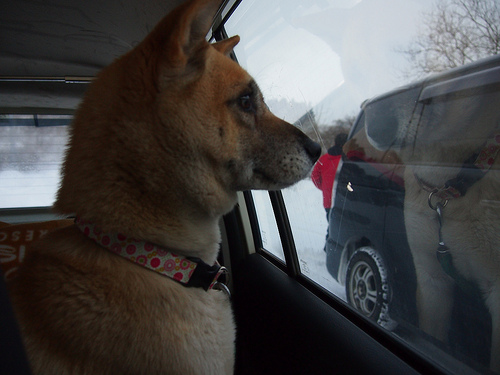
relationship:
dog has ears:
[2, 4, 320, 374] [167, 2, 245, 89]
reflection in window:
[401, 72, 496, 361] [217, 9, 498, 372]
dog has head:
[2, 4, 320, 374] [68, 1, 321, 210]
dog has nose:
[2, 4, 320, 374] [264, 107, 322, 197]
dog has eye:
[2, 4, 320, 374] [229, 80, 266, 118]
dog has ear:
[2, 4, 320, 374] [167, 2, 245, 89]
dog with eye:
[2, 4, 320, 374] [229, 80, 266, 118]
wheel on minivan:
[343, 246, 403, 331] [326, 62, 496, 348]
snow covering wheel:
[338, 239, 397, 334] [343, 246, 403, 331]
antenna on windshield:
[3, 106, 71, 129] [0, 115, 72, 212]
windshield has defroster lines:
[0, 115, 72, 212] [0, 119, 68, 199]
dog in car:
[2, 4, 320, 374] [0, 0, 498, 371]